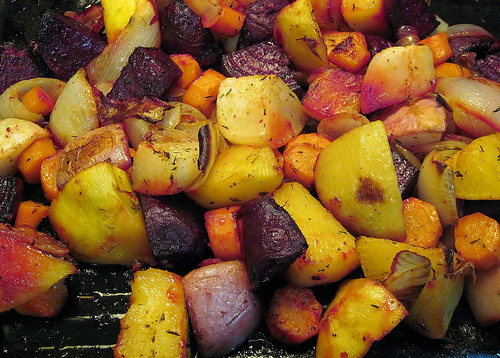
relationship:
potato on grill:
[213, 72, 304, 148] [26, 262, 148, 342]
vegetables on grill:
[119, 77, 327, 288] [26, 262, 148, 342]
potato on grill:
[230, 196, 308, 286] [78, 272, 114, 342]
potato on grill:
[272, 181, 361, 285] [73, 284, 111, 348]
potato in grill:
[272, 181, 361, 285] [31, 260, 127, 357]